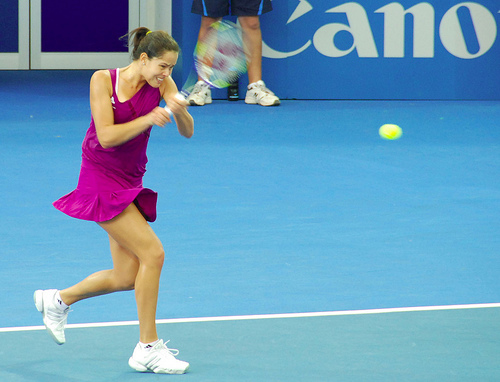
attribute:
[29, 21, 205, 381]
woman — playing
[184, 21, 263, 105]
racquet — moving, blurred, multi coloured, blue, yellow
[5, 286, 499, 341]
line — white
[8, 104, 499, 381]
court — marked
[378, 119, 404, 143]
ball — yellow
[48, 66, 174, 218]
outfit — purple, pink, short, maroon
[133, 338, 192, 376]
shoe — white, tied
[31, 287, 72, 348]
shoe — white, tied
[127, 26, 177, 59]
hair — brown, tied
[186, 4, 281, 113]
person — watching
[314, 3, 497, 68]
letters — white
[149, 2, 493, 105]
wall — blue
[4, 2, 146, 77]
doors — blue, silver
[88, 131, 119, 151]
elbow — bent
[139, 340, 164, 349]
sock — white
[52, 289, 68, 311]
sock — white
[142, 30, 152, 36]
band — yellow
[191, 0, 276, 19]
shorts — black, blue